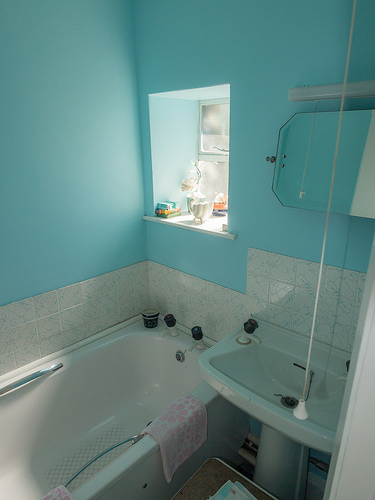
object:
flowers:
[161, 407, 192, 437]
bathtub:
[0, 313, 251, 499]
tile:
[0, 247, 367, 375]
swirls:
[57, 308, 61, 314]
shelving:
[132, 194, 239, 249]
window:
[148, 84, 230, 234]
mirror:
[197, 98, 229, 154]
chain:
[273, 371, 313, 403]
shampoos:
[150, 193, 224, 228]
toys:
[154, 200, 181, 220]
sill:
[140, 202, 234, 244]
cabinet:
[270, 111, 369, 216]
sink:
[197, 315, 353, 497]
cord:
[294, 0, 359, 420]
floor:
[169, 457, 280, 500]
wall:
[0, 0, 375, 495]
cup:
[142, 307, 160, 329]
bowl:
[188, 201, 213, 224]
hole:
[153, 106, 220, 208]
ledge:
[42, 420, 133, 492]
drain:
[280, 395, 299, 409]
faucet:
[160, 313, 180, 337]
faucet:
[186, 326, 205, 352]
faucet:
[238, 318, 263, 344]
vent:
[238, 431, 260, 466]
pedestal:
[252, 423, 309, 499]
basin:
[209, 345, 345, 433]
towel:
[141, 394, 207, 483]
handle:
[0, 361, 63, 397]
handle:
[63, 432, 144, 488]